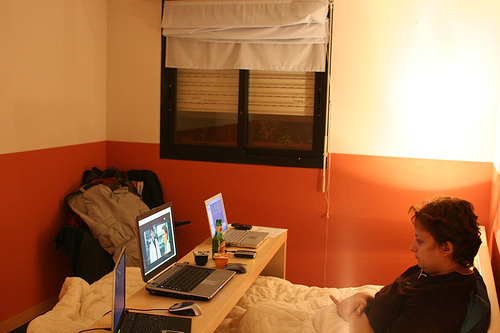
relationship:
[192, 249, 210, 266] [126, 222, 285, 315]
cup on top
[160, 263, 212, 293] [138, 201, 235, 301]
keyboard on laptop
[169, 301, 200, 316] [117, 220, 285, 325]
mouse on table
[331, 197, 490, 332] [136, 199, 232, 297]
person looking at computer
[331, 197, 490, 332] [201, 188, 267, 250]
person looking at computer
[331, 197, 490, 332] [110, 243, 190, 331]
person looking at computer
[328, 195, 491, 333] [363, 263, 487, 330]
person wearing shirt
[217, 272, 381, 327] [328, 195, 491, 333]
blanket on person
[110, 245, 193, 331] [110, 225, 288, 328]
computer on table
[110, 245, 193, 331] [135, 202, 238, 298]
computer on table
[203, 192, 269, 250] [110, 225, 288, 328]
computer on table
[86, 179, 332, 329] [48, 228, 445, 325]
table across bed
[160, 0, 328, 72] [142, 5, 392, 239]
curtain hanging down window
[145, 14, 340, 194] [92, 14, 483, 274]
window on wall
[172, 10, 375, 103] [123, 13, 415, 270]
shade on wall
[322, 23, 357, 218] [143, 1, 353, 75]
cords to curtains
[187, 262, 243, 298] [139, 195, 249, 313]
pad on computer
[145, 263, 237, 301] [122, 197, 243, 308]
keyboard on computer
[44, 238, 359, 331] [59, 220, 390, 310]
bedspread on bed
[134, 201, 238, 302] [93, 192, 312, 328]
computer on table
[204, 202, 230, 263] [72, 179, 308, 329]
bottle on table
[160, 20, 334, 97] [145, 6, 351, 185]
curtain on window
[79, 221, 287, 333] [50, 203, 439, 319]
table across bed